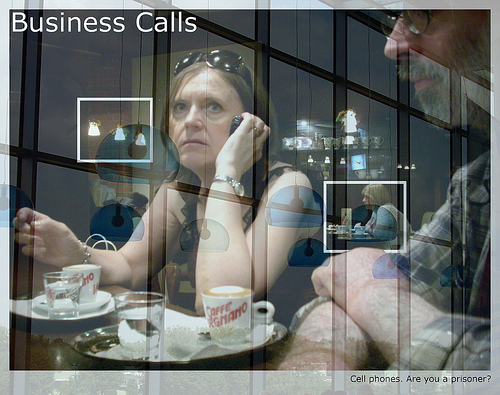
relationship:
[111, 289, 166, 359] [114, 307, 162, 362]
glass containing water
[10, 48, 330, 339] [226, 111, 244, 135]
woman talking on phone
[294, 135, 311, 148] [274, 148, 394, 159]
cup sitting on top of ledge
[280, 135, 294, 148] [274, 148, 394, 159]
cup sitting on top of ledge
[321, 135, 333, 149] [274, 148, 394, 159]
cup sitting on top of ledge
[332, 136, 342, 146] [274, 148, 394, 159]
cup sitting on top of ledge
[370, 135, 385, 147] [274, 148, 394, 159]
cup sitting on top of ledge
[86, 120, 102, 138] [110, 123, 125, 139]
light hanging next to light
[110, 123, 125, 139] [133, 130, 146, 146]
light hanging next to light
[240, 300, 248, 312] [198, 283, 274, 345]
letter printed on coffee cup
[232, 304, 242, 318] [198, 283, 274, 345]
letter printed on coffee cup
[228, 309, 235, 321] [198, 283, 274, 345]
letter printed on coffee cup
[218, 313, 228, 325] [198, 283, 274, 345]
letter printed on coffee cup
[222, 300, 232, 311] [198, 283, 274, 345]
letter printed on coffee cup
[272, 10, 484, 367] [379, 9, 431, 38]
man wearing glasses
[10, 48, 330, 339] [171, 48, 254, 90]
woman wearing glasses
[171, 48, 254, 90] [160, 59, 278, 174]
glasses worn on head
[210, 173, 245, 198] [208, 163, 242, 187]
watch worn on wrist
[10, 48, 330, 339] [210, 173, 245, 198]
woman wearing watch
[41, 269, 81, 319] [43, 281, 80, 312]
glass containing water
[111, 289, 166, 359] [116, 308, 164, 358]
glass containing water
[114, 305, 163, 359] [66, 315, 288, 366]
water sitting on top of plate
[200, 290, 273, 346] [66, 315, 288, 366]
coffee cup sitting on top of plate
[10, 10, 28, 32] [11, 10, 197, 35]
letter forming business calls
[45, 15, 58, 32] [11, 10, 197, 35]
letter forming business calls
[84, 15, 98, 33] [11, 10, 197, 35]
letter forming business calls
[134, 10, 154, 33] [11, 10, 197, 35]
letter forming business calls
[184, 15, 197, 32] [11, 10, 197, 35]
letter forming business calls